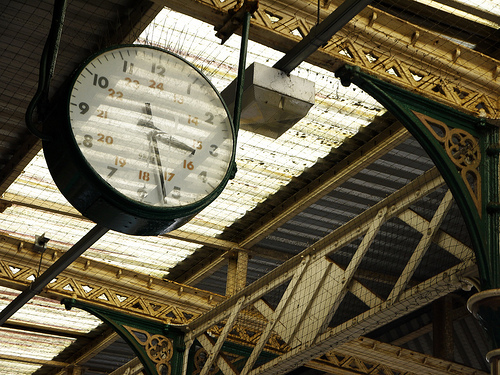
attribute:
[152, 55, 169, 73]
number — small, black, brown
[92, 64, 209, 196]
clock — hanging, spikes, analog, round, long, white, large, black, small, indicating, reflection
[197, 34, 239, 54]
light — fixture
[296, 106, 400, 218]
roof — brown, beautiful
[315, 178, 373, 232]
surface — meshed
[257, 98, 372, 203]
sheet — transparent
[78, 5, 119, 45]
patch — grey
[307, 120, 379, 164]
decoraction — brown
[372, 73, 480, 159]
rod — long, black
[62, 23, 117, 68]
ceiling — grey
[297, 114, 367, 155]
window — glass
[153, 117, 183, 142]
tick — black